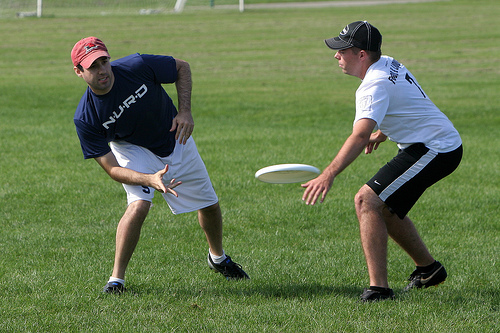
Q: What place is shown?
A: It is a field.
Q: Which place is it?
A: It is a field.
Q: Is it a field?
A: Yes, it is a field.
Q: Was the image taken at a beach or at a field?
A: It was taken at a field.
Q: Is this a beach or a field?
A: It is a field.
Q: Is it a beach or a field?
A: It is a field.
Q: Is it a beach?
A: No, it is a field.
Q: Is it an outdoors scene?
A: Yes, it is outdoors.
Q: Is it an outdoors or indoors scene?
A: It is outdoors.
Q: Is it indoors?
A: No, it is outdoors.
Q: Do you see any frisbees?
A: Yes, there is a frisbee.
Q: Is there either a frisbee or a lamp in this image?
A: Yes, there is a frisbee.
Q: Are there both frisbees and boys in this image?
A: No, there is a frisbee but no boys.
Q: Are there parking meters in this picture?
A: No, there are no parking meters.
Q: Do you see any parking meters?
A: No, there are no parking meters.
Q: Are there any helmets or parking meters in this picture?
A: No, there are no parking meters or helmets.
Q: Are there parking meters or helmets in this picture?
A: No, there are no parking meters or helmets.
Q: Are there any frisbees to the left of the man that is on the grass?
A: Yes, there is a frisbee to the left of the man.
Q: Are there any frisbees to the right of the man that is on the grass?
A: No, the frisbee is to the left of the man.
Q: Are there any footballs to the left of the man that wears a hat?
A: No, there is a frisbee to the left of the man.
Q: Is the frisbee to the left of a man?
A: Yes, the frisbee is to the left of a man.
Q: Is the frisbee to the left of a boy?
A: No, the frisbee is to the left of a man.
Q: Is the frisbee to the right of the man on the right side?
A: No, the frisbee is to the left of the man.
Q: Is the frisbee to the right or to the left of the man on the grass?
A: The frisbee is to the left of the man.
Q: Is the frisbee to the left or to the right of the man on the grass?
A: The frisbee is to the left of the man.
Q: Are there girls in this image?
A: No, there are no girls.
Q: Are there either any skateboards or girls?
A: No, there are no girls or skateboards.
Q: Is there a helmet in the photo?
A: No, there are no helmets.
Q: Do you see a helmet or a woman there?
A: No, there are no helmets or women.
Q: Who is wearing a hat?
A: The man is wearing a hat.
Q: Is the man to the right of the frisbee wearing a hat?
A: Yes, the man is wearing a hat.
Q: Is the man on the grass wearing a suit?
A: No, the man is wearing a hat.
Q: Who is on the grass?
A: The man is on the grass.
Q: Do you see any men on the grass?
A: Yes, there is a man on the grass.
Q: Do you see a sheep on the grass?
A: No, there is a man on the grass.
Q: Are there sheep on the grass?
A: No, there is a man on the grass.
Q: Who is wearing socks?
A: The man is wearing socks.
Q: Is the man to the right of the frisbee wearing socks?
A: Yes, the man is wearing socks.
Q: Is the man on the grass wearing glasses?
A: No, the man is wearing socks.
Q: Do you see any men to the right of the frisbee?
A: Yes, there is a man to the right of the frisbee.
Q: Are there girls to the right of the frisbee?
A: No, there is a man to the right of the frisbee.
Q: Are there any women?
A: No, there are no women.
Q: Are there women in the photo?
A: No, there are no women.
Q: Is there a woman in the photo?
A: No, there are no women.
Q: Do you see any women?
A: No, there are no women.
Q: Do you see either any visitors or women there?
A: No, there are no women or visitors.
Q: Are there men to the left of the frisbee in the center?
A: Yes, there is a man to the left of the frisbee.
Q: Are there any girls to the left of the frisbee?
A: No, there is a man to the left of the frisbee.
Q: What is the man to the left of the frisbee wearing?
A: The man is wearing socks.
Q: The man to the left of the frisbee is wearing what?
A: The man is wearing socks.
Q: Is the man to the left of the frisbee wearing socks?
A: Yes, the man is wearing socks.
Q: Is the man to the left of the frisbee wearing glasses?
A: No, the man is wearing socks.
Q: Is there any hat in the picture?
A: Yes, there is a hat.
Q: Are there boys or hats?
A: Yes, there is a hat.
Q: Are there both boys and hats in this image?
A: No, there is a hat but no boys.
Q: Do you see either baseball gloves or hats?
A: Yes, there is a baseball hat.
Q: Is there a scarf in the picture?
A: No, there are no scarves.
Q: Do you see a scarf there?
A: No, there are no scarves.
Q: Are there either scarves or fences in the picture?
A: No, there are no scarves or fences.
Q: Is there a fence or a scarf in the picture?
A: No, there are no scarves or fences.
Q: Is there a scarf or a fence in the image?
A: No, there are no scarves or fences.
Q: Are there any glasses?
A: No, there are no glasses.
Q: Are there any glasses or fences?
A: No, there are no glasses or fences.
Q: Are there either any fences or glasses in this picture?
A: No, there are no glasses or fences.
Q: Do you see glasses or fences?
A: No, there are no glasses or fences.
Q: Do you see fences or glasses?
A: No, there are no glasses or fences.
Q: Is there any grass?
A: Yes, there is grass.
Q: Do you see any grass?
A: Yes, there is grass.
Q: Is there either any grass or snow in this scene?
A: Yes, there is grass.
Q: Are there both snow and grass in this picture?
A: No, there is grass but no snow.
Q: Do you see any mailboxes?
A: No, there are no mailboxes.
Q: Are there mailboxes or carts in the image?
A: No, there are no mailboxes or carts.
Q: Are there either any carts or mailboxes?
A: No, there are no mailboxes or carts.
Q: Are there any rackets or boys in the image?
A: No, there are no boys or rackets.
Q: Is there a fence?
A: No, there are no fences.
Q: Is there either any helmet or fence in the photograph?
A: No, there are no fences or helmets.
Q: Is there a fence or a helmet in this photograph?
A: No, there are no fences or helmets.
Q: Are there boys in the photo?
A: No, there are no boys.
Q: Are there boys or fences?
A: No, there are no boys or fences.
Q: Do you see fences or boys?
A: No, there are no boys or fences.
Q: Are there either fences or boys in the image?
A: No, there are no boys or fences.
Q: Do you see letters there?
A: Yes, there are letters.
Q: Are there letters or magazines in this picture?
A: Yes, there are letters.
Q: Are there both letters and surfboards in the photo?
A: No, there are letters but no surfboards.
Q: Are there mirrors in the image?
A: No, there are no mirrors.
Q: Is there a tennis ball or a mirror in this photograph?
A: No, there are no mirrors or tennis balls.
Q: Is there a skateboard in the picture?
A: No, there are no skateboards.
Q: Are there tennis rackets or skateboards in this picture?
A: No, there are no skateboards or tennis rackets.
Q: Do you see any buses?
A: No, there are no buses.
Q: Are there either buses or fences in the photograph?
A: No, there are no buses or fences.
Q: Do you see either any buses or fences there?
A: No, there are no buses or fences.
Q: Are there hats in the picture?
A: Yes, there is a hat.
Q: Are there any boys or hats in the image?
A: Yes, there is a hat.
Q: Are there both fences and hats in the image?
A: No, there is a hat but no fences.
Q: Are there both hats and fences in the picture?
A: No, there is a hat but no fences.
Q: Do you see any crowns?
A: No, there are no crowns.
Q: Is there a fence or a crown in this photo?
A: No, there are no crowns or fences.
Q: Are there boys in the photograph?
A: No, there are no boys.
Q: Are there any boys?
A: No, there are no boys.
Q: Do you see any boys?
A: No, there are no boys.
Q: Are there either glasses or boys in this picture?
A: No, there are no boys or glasses.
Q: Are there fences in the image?
A: No, there are no fences.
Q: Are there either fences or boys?
A: No, there are no fences or boys.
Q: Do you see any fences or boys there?
A: No, there are no fences or boys.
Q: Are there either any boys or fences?
A: No, there are no fences or boys.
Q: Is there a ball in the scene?
A: No, there are no balls.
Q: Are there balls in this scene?
A: No, there are no balls.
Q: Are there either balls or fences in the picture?
A: No, there are no balls or fences.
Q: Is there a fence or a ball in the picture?
A: No, there are no balls or fences.